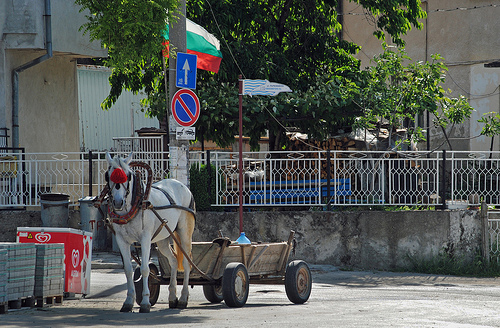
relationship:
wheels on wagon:
[224, 262, 255, 309] [203, 244, 327, 296]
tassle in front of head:
[110, 166, 128, 183] [89, 149, 139, 221]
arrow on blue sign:
[179, 59, 196, 86] [170, 44, 203, 89]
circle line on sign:
[168, 89, 205, 130] [165, 47, 209, 156]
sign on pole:
[171, 87, 200, 127] [166, 0, 193, 184]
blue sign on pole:
[176, 52, 198, 90] [166, 0, 193, 184]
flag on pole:
[235, 73, 292, 97] [235, 78, 245, 234]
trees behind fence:
[321, 37, 409, 134] [219, 149, 466, 215]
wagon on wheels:
[182, 238, 323, 301] [279, 0, 319, 47]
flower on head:
[108, 167, 128, 182] [104, 147, 133, 209]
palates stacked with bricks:
[183, 236, 327, 303] [0, 238, 67, 299]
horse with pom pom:
[95, 146, 197, 314] [104, 153, 130, 186]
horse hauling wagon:
[105, 151, 196, 313] [131, 238, 312, 307]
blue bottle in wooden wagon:
[232, 229, 254, 247] [132, 225, 316, 310]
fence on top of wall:
[0, 149, 499, 214] [1, 203, 498, 275]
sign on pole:
[169, 87, 203, 126] [163, 0, 192, 188]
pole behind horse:
[163, 0, 192, 188] [95, 146, 197, 314]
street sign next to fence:
[236, 75, 294, 231] [0, 151, 499, 207]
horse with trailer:
[105, 151, 196, 313] [136, 244, 311, 308]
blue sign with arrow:
[176, 52, 198, 90] [181, 56, 190, 84]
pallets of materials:
[1, 240, 70, 312] [6, 232, 88, 296]